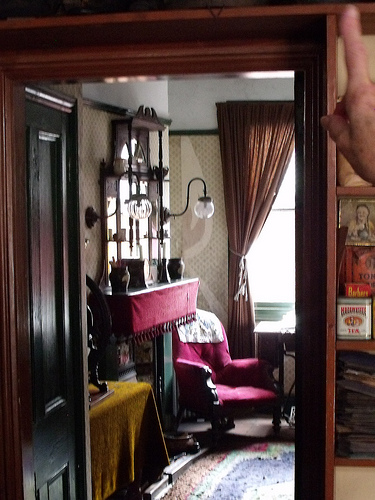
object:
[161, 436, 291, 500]
light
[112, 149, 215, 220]
lights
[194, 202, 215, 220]
bulb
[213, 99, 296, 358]
curtain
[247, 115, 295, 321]
window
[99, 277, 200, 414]
table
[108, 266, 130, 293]
vases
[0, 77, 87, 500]
door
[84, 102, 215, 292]
antique containers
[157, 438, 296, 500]
carpet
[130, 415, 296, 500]
ground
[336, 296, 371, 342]
container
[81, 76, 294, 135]
wall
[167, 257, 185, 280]
vase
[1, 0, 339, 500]
doorway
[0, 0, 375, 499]
room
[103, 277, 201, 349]
cloth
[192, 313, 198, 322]
tassel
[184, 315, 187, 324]
tassel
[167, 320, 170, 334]
tassel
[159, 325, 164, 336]
tassel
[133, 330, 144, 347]
tassel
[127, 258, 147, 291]
clock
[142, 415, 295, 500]
surface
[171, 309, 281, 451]
chair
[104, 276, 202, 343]
mantlepiece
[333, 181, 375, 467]
shelf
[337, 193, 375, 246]
photograph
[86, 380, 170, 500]
cloth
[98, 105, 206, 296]
poles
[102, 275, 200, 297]
top